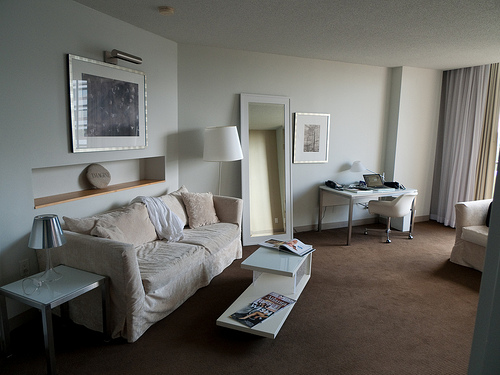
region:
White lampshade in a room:
[200, 122, 242, 162]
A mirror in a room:
[237, 92, 294, 242]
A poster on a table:
[228, 291, 294, 329]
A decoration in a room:
[84, 163, 111, 189]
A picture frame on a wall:
[291, 111, 330, 163]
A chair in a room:
[362, 192, 416, 242]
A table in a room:
[315, 180, 416, 242]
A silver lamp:
[28, 213, 68, 283]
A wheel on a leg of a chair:
[385, 239, 391, 244]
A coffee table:
[213, 240, 313, 339]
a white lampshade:
[203, 121, 242, 161]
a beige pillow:
[175, 187, 220, 227]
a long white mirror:
[240, 93, 295, 243]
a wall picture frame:
[290, 111, 330, 163]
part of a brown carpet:
[326, 236, 442, 365]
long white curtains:
[428, 64, 486, 227]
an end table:
[5, 263, 107, 336]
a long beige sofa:
[48, 187, 248, 338]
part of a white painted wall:
[217, 55, 353, 91]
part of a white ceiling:
[300, 4, 492, 60]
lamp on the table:
[26, 215, 66, 282]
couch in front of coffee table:
[35, 182, 252, 342]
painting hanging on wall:
[65, 54, 155, 154]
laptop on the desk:
[362, 173, 394, 193]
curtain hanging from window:
[430, 64, 498, 234]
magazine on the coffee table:
[258, 237, 314, 259]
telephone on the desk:
[323, 178, 345, 193]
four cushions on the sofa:
[62, 184, 227, 248]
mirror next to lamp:
[236, 91, 296, 247]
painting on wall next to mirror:
[290, 112, 331, 164]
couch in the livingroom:
[60, 180, 245, 325]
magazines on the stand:
[222, 280, 299, 341]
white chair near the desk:
[359, 192, 424, 244]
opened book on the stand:
[255, 229, 316, 261]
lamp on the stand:
[21, 205, 71, 296]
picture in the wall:
[292, 108, 332, 167]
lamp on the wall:
[103, 36, 150, 68]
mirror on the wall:
[231, 85, 293, 242]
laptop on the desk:
[357, 170, 387, 189]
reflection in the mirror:
[255, 119, 282, 229]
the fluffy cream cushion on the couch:
[62, 213, 98, 234]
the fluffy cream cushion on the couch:
[95, 199, 157, 249]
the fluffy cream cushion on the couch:
[152, 185, 190, 225]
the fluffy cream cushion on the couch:
[181, 191, 218, 228]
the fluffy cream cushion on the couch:
[462, 223, 492, 246]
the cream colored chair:
[365, 188, 415, 243]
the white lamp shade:
[202, 123, 246, 163]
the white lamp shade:
[348, 157, 365, 173]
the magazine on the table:
[227, 301, 269, 327]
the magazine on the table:
[260, 288, 293, 312]